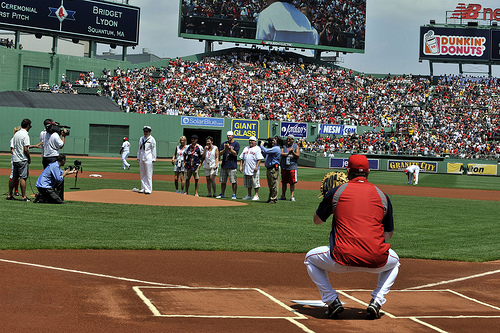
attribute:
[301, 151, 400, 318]
catcher — crouching, squatting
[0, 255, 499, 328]
lines — white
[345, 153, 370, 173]
cap — red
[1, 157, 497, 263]
grass — lush, green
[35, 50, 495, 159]
spectators — watching, crowd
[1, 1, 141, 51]
billboard — large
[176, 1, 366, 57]
billboard — large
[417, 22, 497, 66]
billboard — large, pink, orange,& white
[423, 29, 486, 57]
logo — dunkin' donuts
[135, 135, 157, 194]
uniform — white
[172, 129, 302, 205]
people — standing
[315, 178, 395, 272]
shirt — orange, gray, &black, red, black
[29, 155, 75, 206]
man — kneeling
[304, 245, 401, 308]
pants — white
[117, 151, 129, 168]
pants — white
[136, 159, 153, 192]
pants — white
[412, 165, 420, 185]
pants — white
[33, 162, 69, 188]
shirt — blue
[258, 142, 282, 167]
shirt — blue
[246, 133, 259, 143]
cap — white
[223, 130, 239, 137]
cap — white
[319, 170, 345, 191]
glove — yellow